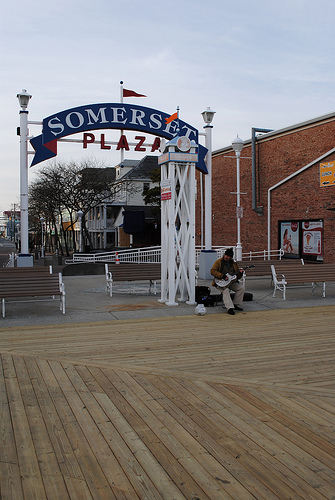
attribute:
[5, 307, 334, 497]
sidewalk — brown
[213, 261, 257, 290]
guitar — played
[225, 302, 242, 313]
shoes — black